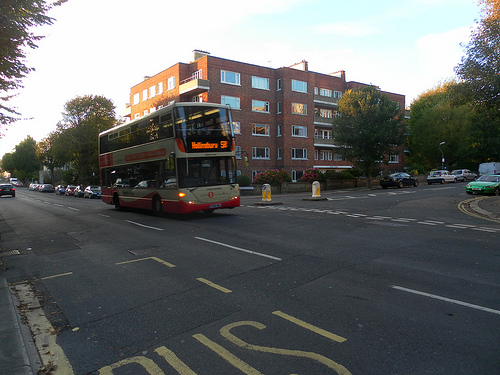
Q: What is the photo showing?
A: It is showing a street.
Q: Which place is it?
A: It is a street.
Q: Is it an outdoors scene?
A: Yes, it is outdoors.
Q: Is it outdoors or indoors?
A: It is outdoors.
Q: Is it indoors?
A: No, it is outdoors.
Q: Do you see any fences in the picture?
A: No, there are no fences.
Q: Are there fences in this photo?
A: No, there are no fences.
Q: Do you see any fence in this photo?
A: No, there are no fences.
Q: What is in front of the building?
A: The tree is in front of the building.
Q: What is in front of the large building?
A: The tree is in front of the building.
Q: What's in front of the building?
A: The tree is in front of the building.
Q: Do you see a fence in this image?
A: No, there are no fences.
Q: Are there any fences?
A: No, there are no fences.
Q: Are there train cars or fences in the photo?
A: No, there are no fences or train cars.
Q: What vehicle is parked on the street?
A: The vehicle is a car.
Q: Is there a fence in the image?
A: No, there are no fences.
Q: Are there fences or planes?
A: No, there are no fences or planes.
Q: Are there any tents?
A: No, there are no tents.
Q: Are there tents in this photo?
A: No, there are no tents.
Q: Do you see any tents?
A: No, there are no tents.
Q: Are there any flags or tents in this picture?
A: No, there are no tents or flags.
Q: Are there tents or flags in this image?
A: No, there are no tents or flags.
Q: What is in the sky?
A: The clouds are in the sky.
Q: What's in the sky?
A: The clouds are in the sky.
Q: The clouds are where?
A: The clouds are in the sky.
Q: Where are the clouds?
A: The clouds are in the sky.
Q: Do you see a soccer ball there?
A: No, there are no soccer balls.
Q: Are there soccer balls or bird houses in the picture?
A: No, there are no soccer balls or bird houses.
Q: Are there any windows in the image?
A: Yes, there is a window.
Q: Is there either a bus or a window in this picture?
A: Yes, there is a window.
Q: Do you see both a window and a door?
A: No, there is a window but no doors.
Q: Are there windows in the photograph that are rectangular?
A: Yes, there is a rectangular window.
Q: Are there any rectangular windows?
A: Yes, there is a rectangular window.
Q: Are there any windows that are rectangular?
A: Yes, there is a window that is rectangular.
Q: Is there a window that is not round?
A: Yes, there is a rectangular window.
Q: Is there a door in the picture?
A: No, there are no doors.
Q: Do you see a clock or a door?
A: No, there are no doors or clocks.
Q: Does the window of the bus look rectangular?
A: Yes, the window is rectangular.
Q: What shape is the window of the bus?
A: The window is rectangular.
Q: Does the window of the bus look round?
A: No, the window is rectangular.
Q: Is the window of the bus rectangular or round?
A: The window is rectangular.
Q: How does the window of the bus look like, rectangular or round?
A: The window is rectangular.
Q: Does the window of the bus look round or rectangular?
A: The window is rectangular.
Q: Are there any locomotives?
A: No, there are no locomotives.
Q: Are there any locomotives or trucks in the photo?
A: No, there are no locomotives or trucks.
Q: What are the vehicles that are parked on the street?
A: The vehicles are cars.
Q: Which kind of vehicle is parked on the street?
A: The vehicles are cars.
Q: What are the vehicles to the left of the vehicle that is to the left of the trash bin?
A: The vehicles are cars.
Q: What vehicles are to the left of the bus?
A: The vehicles are cars.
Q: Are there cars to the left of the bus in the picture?
A: Yes, there are cars to the left of the bus.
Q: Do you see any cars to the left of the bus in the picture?
A: Yes, there are cars to the left of the bus.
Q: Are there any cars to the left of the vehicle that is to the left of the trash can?
A: Yes, there are cars to the left of the bus.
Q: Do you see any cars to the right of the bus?
A: No, the cars are to the left of the bus.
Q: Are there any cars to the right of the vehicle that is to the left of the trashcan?
A: No, the cars are to the left of the bus.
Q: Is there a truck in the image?
A: No, there are no trucks.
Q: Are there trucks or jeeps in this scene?
A: No, there are no trucks or jeeps.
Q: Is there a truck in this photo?
A: No, there are no trucks.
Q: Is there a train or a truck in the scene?
A: No, there are no trucks or trains.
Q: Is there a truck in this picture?
A: No, there are no trucks.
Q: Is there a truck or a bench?
A: No, there are no trucks or benches.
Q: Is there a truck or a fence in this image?
A: No, there are no trucks or fences.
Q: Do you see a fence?
A: No, there are no fences.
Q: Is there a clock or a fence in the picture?
A: No, there are no fences or clocks.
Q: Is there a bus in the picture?
A: Yes, there is a bus.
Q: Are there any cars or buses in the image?
A: Yes, there is a bus.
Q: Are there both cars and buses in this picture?
A: Yes, there are both a bus and a car.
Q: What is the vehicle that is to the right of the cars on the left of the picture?
A: The vehicle is a bus.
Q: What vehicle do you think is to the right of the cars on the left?
A: The vehicle is a bus.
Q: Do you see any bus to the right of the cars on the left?
A: Yes, there is a bus to the right of the cars.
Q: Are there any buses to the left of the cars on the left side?
A: No, the bus is to the right of the cars.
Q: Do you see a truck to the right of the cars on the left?
A: No, there is a bus to the right of the cars.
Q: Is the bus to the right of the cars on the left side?
A: Yes, the bus is to the right of the cars.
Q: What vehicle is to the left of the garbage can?
A: The vehicle is a bus.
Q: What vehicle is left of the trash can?
A: The vehicle is a bus.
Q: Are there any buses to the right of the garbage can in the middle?
A: No, the bus is to the left of the garbage bin.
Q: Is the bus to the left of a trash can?
A: Yes, the bus is to the left of a trash can.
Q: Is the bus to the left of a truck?
A: No, the bus is to the left of a trash can.